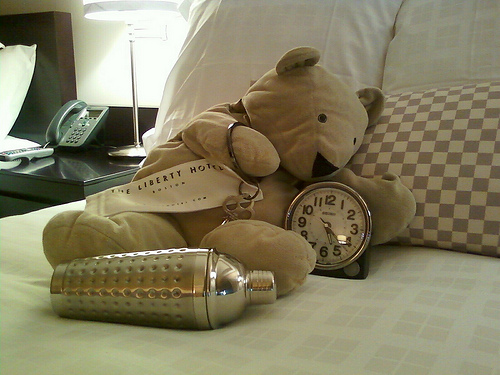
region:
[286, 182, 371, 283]
A metal alarm clock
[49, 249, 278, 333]
A metal drink shaker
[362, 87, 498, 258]
A checkered patterned pillow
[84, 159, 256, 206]
A label for The Liberty Hotel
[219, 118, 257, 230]
A key on a keyring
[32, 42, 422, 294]
A teddy bear on a bed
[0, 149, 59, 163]
A television remote control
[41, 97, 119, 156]
An elevated telephone system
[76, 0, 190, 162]
A lamp on the night stand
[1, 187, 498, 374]
A relaxing and confortable hotel bed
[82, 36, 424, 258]
teddy bear on bed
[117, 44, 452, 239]
cute teddy bear on bed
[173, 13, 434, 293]
fluffy teddy bear on bed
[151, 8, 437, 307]
cute fluffy teddy bear on bed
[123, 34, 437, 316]
adorable teddy bear on bed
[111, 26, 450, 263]
teddy bear with clock on bed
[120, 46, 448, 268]
brown teddy bear on bed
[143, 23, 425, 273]
teddy bear with a small clock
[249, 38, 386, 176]
head of a teddy bear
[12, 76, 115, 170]
phone on a night stand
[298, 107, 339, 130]
eye of the doll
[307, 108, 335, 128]
a small dot in dall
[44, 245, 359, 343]
a water bottle in bed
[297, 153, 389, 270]
a small clock in bed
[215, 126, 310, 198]
hand of the doll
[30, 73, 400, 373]
a cute bear in bed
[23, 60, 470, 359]
a small doll in bed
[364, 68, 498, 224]
a pillow on the bed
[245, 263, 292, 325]
mouth of the bottle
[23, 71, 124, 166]
a telephone on table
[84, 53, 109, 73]
this is the wall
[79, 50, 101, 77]
the wall is white in color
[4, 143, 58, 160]
this is a remote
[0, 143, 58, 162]
the remote is grey in color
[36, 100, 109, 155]
this is a telephone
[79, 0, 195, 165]
this is a lamp shade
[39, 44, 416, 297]
this is a teddy bear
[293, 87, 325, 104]
the teddy is cream in color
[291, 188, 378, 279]
this is a watch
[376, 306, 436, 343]
the sheet is white in color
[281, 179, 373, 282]
clock sitting on a bed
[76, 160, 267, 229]
white tag attached to a key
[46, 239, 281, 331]
silver metallic thermos bottle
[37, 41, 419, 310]
brown teddy bear sitting on a bed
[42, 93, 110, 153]
telephone on a black end table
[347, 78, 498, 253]
checker patterned pillow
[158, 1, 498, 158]
big fluffy white pillows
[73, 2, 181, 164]
bright white lamp on end table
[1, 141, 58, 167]
TV remote sitting on end table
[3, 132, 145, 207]
end table between beds is black